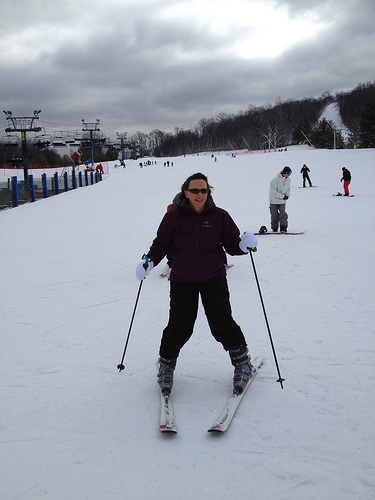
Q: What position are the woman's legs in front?
A: A "V".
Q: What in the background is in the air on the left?
A: The ski lift.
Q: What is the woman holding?
A: Ski poles.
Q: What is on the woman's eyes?
A: Sunglasses.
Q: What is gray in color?
A: The boots.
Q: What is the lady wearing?
A: Snow gear.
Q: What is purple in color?
A: The jacket.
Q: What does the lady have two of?
A: Poles.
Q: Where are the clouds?
A: Above the snow.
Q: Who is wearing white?
A: A person.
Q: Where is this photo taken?
A: A skiing resort.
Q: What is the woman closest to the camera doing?
A: Skiing.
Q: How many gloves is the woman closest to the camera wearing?
A: Two.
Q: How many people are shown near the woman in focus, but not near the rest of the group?
A: Three.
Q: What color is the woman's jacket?
A: Purple.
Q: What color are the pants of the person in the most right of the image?
A: Red.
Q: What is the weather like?
A: Partly cloudy.